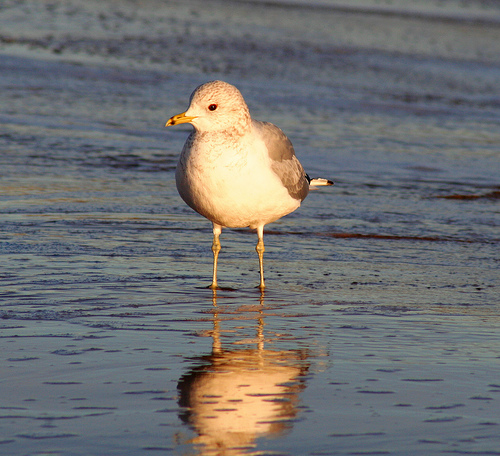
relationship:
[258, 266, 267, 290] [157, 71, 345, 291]
leg of bird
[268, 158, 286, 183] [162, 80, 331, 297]
feather of bird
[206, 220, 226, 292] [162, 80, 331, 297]
leg of bird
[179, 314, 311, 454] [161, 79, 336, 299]
reflection of seagull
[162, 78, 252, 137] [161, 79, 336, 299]
head on seagull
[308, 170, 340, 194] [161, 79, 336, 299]
tail on seagull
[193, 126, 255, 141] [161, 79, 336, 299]
seagull neck on seagull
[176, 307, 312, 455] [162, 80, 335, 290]
reflection of bird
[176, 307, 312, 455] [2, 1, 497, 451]
reflection of gull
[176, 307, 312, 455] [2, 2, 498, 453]
reflection in water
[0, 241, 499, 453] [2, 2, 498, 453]
ripples in water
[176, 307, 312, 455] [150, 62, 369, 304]
reflection from bird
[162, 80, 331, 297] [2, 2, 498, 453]
bird standing in water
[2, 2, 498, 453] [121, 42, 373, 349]
water surrounds bird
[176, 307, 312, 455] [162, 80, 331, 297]
reflection from bird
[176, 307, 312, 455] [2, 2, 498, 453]
reflection on water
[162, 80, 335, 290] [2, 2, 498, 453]
bird in water